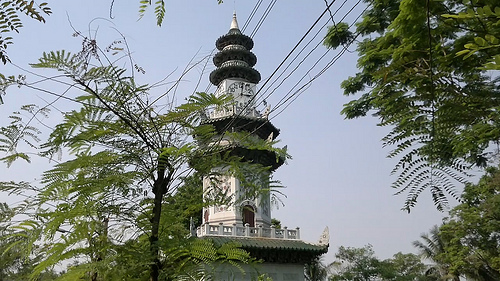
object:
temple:
[165, 0, 300, 243]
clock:
[229, 79, 253, 106]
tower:
[200, 0, 281, 240]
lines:
[286, 37, 298, 55]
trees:
[457, 0, 499, 93]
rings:
[228, 72, 238, 78]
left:
[1, 80, 59, 95]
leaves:
[25, 6, 40, 14]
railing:
[238, 225, 276, 238]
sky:
[156, 24, 177, 33]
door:
[238, 202, 256, 227]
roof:
[201, 236, 334, 263]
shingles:
[225, 237, 237, 243]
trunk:
[145, 245, 163, 273]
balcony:
[181, 212, 250, 238]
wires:
[268, 58, 285, 71]